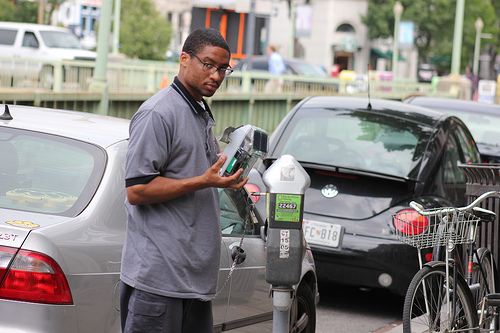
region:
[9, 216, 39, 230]
A paw shaped decal on the trunk of a car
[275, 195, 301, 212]
Identifying numbers on a parking meter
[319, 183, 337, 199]
A Volkswagen logo on the trunk of a car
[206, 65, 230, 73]
A man wearing glasses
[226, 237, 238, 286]
A silver chain attached to a key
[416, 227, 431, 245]
Wires that form a bicycle basket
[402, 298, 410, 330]
Black rubber bicycle tire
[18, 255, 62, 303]
A car's red and white tail and brake light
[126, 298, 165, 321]
The pocket flap on a man's pants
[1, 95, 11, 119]
The antenna of a car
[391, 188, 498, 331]
bicycle with a basket in front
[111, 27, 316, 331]
man collecting money from a parking meter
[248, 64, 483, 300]
parked black car, view from the back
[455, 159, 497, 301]
metal garbage can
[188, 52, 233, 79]
black-framed eyeglasses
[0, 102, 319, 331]
gray parked car behind parking meter and man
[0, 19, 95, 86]
white van with blurred words on the side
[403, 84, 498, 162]
back part of parked car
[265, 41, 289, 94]
blurry man dressed in a blue shirt and khaki pants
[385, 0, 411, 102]
blurry, light green lamp post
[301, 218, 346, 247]
licence plate on the back of car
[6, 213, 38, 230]
yellow paw sticker on the back of trunk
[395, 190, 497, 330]
bicycle with a basket on the sidewalk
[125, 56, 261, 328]
man checking parking meter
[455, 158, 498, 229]
metal trash can on the sidewalk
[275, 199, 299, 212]
white numbers on a parking meter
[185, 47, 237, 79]
man wearing glasses with black rims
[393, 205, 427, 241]
red circle light on the back of car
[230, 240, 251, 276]
black door handle on sliver car door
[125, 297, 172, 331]
pocket on mans pants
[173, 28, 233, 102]
head of a person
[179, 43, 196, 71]
ear of a person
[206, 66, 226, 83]
nose of a person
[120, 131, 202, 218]
arm of a person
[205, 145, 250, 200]
hand of a person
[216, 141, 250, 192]
fingers of a person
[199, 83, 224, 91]
mouth of a person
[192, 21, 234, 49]
hair of a person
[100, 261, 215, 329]
legs of a person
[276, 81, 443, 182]
windows of a beetle car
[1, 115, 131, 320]
THAT IS A CAR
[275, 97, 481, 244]
THAT IS A CAR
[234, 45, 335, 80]
THAT IS A CAR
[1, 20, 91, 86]
THAT IS A CAR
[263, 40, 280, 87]
THAT IS A PERSON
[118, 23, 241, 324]
THAT IS A PERSON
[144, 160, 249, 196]
A HAND OF A PERSON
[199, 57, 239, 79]
THE PERSON WEARING SPECTACLES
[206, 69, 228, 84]
THE NOSE OF THE PERSON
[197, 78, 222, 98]
THE MOUTH OF THE PERSON